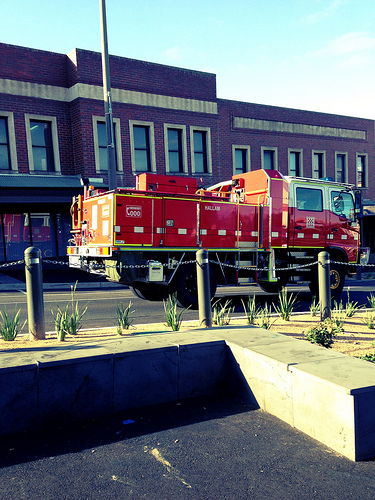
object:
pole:
[23, 246, 45, 339]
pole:
[194, 248, 212, 331]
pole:
[317, 251, 331, 323]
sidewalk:
[3, 283, 126, 292]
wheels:
[169, 263, 218, 309]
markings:
[141, 442, 194, 490]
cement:
[198, 431, 293, 476]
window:
[0, 115, 10, 171]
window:
[96, 120, 117, 169]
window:
[133, 126, 151, 172]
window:
[166, 128, 184, 172]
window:
[193, 130, 208, 173]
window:
[233, 149, 244, 175]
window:
[289, 150, 298, 177]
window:
[335, 155, 345, 181]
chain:
[0, 258, 375, 273]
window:
[29, 117, 53, 170]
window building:
[125, 114, 159, 173]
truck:
[65, 168, 364, 310]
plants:
[161, 291, 192, 332]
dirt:
[345, 332, 373, 351]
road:
[43, 287, 127, 318]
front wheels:
[306, 262, 344, 300]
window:
[263, 149, 274, 169]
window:
[312, 151, 323, 178]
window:
[335, 153, 344, 182]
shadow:
[0, 339, 261, 469]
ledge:
[0, 323, 375, 463]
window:
[355, 152, 366, 189]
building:
[0, 43, 374, 272]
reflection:
[4, 212, 53, 245]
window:
[4, 211, 51, 245]